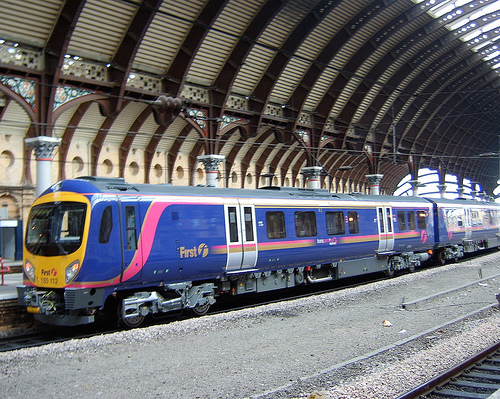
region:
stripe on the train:
[93, 199, 190, 296]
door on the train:
[375, 204, 400, 259]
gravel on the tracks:
[358, 310, 499, 395]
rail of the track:
[398, 342, 498, 397]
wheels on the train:
[88, 252, 435, 344]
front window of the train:
[13, 195, 95, 262]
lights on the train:
[22, 260, 82, 280]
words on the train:
[173, 242, 198, 264]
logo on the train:
[194, 237, 212, 264]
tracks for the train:
[416, 337, 498, 395]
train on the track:
[24, 163, 494, 308]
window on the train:
[22, 205, 79, 252]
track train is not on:
[425, 349, 495, 394]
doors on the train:
[230, 199, 252, 267]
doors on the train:
[371, 206, 401, 255]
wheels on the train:
[182, 285, 216, 315]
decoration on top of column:
[18, 126, 64, 155]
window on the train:
[267, 212, 288, 242]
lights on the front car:
[20, 250, 80, 287]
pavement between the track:
[75, 308, 400, 377]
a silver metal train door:
[223, 205, 259, 274]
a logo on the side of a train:
[176, 243, 211, 259]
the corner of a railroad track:
[396, 340, 498, 396]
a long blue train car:
[18, 173, 440, 334]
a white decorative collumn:
[23, 134, 58, 193]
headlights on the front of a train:
[63, 260, 78, 282]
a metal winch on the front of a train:
[31, 288, 56, 313]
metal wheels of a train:
[123, 283, 220, 327]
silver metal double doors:
[378, 205, 398, 250]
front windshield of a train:
[26, 203, 87, 255]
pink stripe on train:
[62, 208, 442, 283]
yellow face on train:
[11, 187, 103, 309]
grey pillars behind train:
[17, 127, 52, 207]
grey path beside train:
[120, 271, 394, 396]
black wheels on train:
[87, 281, 229, 329]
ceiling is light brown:
[78, 1, 306, 89]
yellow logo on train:
[182, 223, 233, 280]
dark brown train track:
[405, 334, 492, 395]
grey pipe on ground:
[361, 268, 489, 333]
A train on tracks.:
[3, 181, 499, 276]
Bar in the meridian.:
[395, 263, 499, 312]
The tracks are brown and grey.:
[445, 355, 499, 396]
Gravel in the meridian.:
[209, 300, 369, 377]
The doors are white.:
[221, 205, 266, 270]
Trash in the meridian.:
[367, 309, 465, 353]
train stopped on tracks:
[10, 161, 497, 341]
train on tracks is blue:
[17, 155, 498, 335]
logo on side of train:
[192, 238, 209, 258]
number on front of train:
[28, 273, 64, 288]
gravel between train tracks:
[2, 252, 499, 397]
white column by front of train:
[22, 130, 67, 252]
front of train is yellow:
[19, 187, 94, 294]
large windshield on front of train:
[15, 197, 90, 259]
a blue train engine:
[19, 177, 432, 328]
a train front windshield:
[25, 202, 86, 256]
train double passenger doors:
[223, 198, 256, 271]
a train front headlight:
[65, 258, 80, 281]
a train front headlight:
[22, 257, 34, 282]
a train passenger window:
[264, 212, 287, 239]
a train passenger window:
[294, 210, 319, 237]